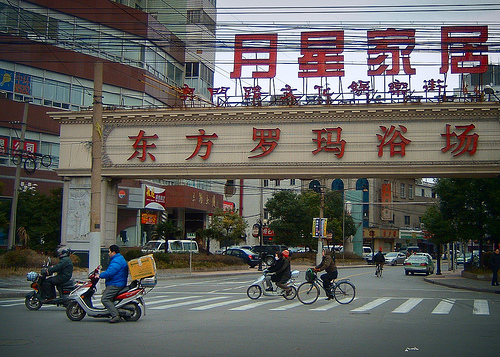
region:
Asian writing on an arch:
[73, 96, 498, 169]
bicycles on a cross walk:
[224, 235, 381, 316]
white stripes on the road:
[367, 289, 499, 327]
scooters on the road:
[2, 238, 159, 355]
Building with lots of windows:
[3, 3, 250, 113]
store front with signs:
[138, 165, 251, 260]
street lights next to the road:
[296, 199, 363, 300]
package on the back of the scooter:
[74, 235, 166, 327]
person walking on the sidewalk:
[467, 239, 499, 297]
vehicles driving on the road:
[377, 227, 479, 304]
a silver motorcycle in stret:
[60, 262, 157, 321]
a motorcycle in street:
[21, 257, 84, 312]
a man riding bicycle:
[293, 248, 356, 304]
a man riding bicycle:
[245, 248, 295, 300]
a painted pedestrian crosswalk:
[6, 288, 498, 313]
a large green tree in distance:
[267, 187, 356, 252]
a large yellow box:
[126, 254, 156, 279]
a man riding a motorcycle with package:
[62, 244, 158, 320]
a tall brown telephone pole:
[90, 59, 101, 270]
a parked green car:
[402, 254, 432, 277]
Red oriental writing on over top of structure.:
[118, 121, 485, 162]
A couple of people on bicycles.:
[296, 243, 386, 303]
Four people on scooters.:
[25, 237, 302, 323]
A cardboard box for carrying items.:
[126, 251, 161, 281]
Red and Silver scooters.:
[21, 262, 161, 322]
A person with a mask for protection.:
[264, 247, 286, 292]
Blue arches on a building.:
[302, 180, 376, 229]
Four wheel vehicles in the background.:
[142, 238, 490, 283]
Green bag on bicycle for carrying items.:
[298, 265, 363, 310]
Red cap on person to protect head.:
[274, 245, 301, 298]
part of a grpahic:
[234, 12, 289, 96]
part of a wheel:
[124, 295, 146, 314]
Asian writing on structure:
[122, 23, 497, 176]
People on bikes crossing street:
[233, 225, 358, 310]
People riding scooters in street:
[21, 237, 153, 332]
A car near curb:
[401, 247, 435, 284]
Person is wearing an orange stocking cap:
[273, 237, 293, 275]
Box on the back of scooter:
[91, 241, 158, 315]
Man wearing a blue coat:
[93, 235, 127, 293]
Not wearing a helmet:
[103, 242, 125, 263]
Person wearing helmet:
[49, 234, 72, 261]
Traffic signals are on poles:
[291, 175, 373, 246]